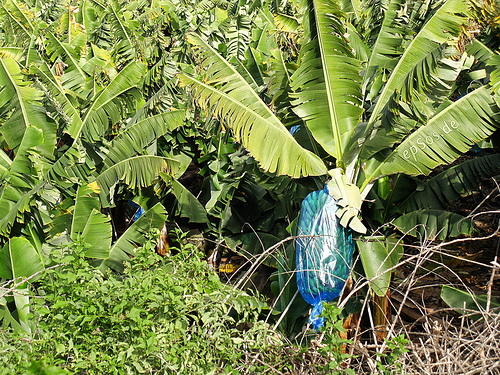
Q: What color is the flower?
A: Blue.